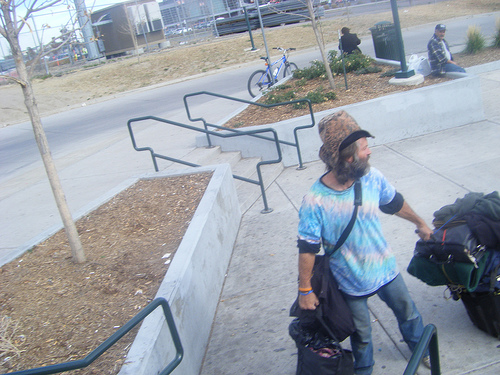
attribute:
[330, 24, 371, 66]
person — sitting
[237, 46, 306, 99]
bike — parked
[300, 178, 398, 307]
teeshirt — blue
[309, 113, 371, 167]
hat — brown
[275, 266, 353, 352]
bag — black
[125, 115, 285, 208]
railings — black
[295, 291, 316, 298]
bracelet — blue